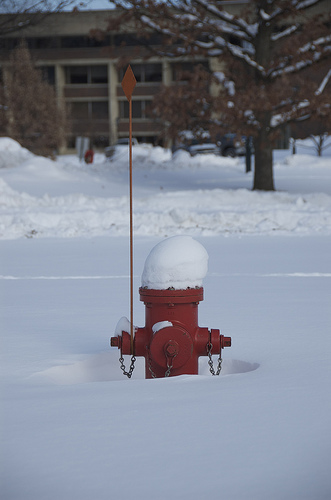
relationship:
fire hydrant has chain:
[111, 236, 232, 376] [117, 354, 226, 373]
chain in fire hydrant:
[117, 354, 226, 373] [111, 236, 232, 376]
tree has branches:
[112, 0, 330, 199] [126, 0, 329, 88]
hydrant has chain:
[111, 236, 232, 376] [117, 354, 226, 373]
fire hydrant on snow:
[111, 236, 232, 376] [57, 220, 290, 441]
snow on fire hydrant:
[139, 234, 211, 288] [105, 278, 236, 377]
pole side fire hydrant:
[119, 101, 148, 351] [105, 278, 236, 377]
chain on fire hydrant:
[117, 354, 226, 373] [112, 287, 235, 383]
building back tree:
[3, 7, 291, 150] [112, 0, 330, 199]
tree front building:
[112, 0, 330, 199] [0, 2, 235, 154]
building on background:
[3, 7, 327, 151] [5, 19, 322, 133]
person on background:
[86, 144, 98, 161] [17, 121, 289, 164]